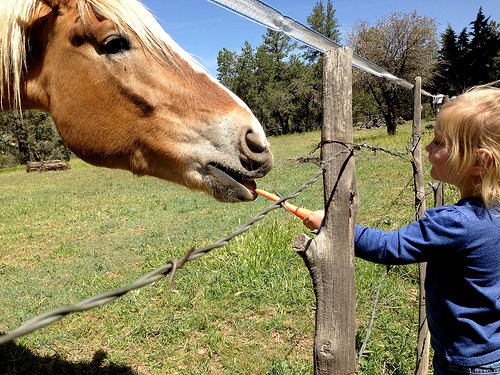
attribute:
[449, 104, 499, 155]
hair — blonde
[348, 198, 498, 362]
shirt — blue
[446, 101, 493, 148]
hair — light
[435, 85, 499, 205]
hair — wind blown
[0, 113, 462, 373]
pasture — green, grassy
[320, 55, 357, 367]
post — wooden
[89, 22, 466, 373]
fence — wooden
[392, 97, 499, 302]
she — blonde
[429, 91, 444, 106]
ribbon — long, white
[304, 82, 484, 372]
girl — very young, little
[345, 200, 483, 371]
shirt — blue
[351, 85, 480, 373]
shirt — blue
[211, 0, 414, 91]
strap — white, blue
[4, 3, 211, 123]
mane — blonde